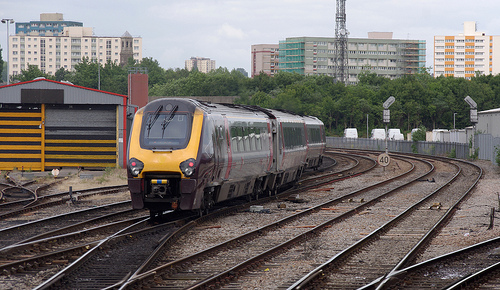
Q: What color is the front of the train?
A: Yellow.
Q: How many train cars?
A: Three.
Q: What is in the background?
A: Buildings.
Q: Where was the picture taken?
A: On track.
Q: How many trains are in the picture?
A: 1.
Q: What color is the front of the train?
A: Yellow.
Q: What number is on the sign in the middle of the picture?
A: 40.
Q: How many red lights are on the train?
A: 2.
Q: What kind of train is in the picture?
A: Passenger train.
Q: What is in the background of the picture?
A: Buildings.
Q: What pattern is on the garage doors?
A: Stripes.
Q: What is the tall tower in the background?
A: Phone tower.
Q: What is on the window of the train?
A: Windshield wipers.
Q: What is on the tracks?
A: A train.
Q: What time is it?
A: Afternoon.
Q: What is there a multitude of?
A: Train tracks.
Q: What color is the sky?
A: Blue.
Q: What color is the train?
A: Silver and yellow.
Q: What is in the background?
A: Buildings.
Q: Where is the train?
A: On the tracks.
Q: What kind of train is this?
A: Passenger.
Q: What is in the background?
A: A city.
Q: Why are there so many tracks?
A: For other trains to use.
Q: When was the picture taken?
A: During the day.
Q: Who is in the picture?
A: No one.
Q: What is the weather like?
A: Partly cloudy.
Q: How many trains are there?
A: One.